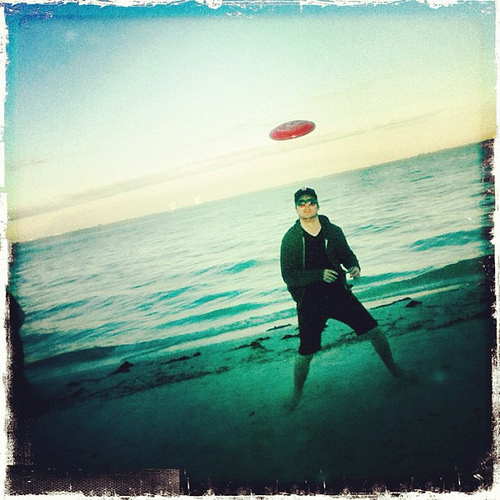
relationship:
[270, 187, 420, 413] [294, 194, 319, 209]
man wearing sunglasses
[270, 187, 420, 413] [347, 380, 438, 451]
man on sand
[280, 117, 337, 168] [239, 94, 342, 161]
freesbee in air